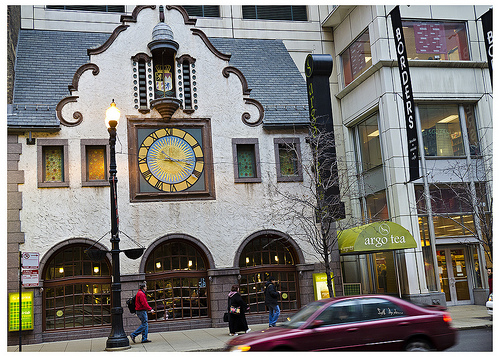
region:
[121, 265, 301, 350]
People walking on the street.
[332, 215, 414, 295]
An awning with the name of a business.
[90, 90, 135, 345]
A streetlight.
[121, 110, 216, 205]
A clock.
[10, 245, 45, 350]
A street sign.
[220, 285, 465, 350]
A red car.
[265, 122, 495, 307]
The trees have no leaves on them.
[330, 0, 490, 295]
A multistory building with large windows.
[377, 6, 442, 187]
A black banner for a business.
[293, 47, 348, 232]
A large business sign attached to a building.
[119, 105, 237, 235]
large clock on building front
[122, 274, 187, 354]
person walking on sidewalk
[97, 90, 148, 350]
lights on pole on sidewalk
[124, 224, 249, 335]
entrance to building behind railing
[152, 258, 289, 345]
decorative brick railing on sidewalk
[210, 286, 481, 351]
red car driving on road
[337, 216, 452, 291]
green and white awning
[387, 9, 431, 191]
black and white sign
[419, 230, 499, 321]
double doors into building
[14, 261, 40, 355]
red and white sign on pole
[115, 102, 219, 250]
large clock on building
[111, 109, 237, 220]
large blue and yellow clock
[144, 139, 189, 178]
yellow sun in the center of the clock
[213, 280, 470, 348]
red car parked on the side of the street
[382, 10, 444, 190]
black borders banner on the street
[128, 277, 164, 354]
man with red shirt and black backpack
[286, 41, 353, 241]
black sign on side of street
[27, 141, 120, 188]
small windows above shop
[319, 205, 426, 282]
green arch awning says argo tea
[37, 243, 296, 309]
lights on the inside on the store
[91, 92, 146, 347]
black post with old fashioned style street lamp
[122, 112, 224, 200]
the clock on the wall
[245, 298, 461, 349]
the red color car on the road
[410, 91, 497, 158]
the glass window of the building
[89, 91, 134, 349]
the street lamp on the street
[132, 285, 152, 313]
the red color jacket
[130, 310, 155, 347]
the blue color jeans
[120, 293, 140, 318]
the black color bag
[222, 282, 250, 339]
the women standing on the road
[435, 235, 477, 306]
the door of the building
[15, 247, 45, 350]
the sign boards in white color